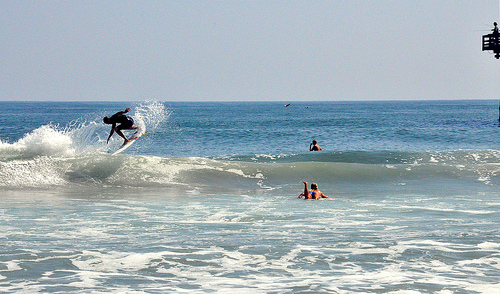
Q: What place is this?
A: It is an ocean.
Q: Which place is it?
A: It is an ocean.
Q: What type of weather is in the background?
A: It is clear.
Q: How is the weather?
A: It is clear.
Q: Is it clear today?
A: Yes, it is clear.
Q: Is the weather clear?
A: Yes, it is clear.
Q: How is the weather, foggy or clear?
A: It is clear.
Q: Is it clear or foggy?
A: It is clear.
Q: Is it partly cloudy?
A: No, it is clear.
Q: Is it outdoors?
A: Yes, it is outdoors.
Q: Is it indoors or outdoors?
A: It is outdoors.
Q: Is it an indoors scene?
A: No, it is outdoors.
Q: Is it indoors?
A: No, it is outdoors.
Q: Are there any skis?
A: No, there are no skis.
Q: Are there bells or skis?
A: No, there are no skis or bells.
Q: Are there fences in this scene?
A: No, there are no fences.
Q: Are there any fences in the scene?
A: No, there are no fences.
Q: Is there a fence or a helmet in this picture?
A: No, there are no fences or helmets.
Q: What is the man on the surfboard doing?
A: The man is surfing.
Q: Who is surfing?
A: The man is surfing.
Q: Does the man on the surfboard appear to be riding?
A: No, the man is surfing.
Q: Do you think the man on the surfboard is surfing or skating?
A: The man is surfing.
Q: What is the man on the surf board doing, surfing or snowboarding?
A: The man is surfing.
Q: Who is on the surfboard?
A: The man is on the surfboard.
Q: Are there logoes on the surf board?
A: No, there is a man on the surf board.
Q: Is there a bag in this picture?
A: No, there are no bags.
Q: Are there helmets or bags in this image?
A: No, there are no bags or helmets.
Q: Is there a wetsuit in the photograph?
A: Yes, there is a wetsuit.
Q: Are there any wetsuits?
A: Yes, there is a wetsuit.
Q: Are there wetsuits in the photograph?
A: Yes, there is a wetsuit.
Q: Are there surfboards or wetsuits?
A: Yes, there is a wetsuit.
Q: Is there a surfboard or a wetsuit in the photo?
A: Yes, there is a wetsuit.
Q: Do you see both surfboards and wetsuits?
A: Yes, there are both a wetsuit and a surfboard.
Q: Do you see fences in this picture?
A: No, there are no fences.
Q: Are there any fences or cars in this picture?
A: No, there are no fences or cars.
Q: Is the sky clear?
A: Yes, the sky is clear.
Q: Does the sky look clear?
A: Yes, the sky is clear.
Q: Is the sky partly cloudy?
A: No, the sky is clear.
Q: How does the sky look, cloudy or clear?
A: The sky is clear.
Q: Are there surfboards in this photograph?
A: Yes, there is a surfboard.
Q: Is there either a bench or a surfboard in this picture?
A: Yes, there is a surfboard.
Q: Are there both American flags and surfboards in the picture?
A: No, there is a surfboard but no American flags.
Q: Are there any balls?
A: No, there are no balls.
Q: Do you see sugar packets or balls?
A: No, there are no balls or sugar packets.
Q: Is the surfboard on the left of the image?
A: Yes, the surfboard is on the left of the image.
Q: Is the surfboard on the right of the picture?
A: No, the surfboard is on the left of the image.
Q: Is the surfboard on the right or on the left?
A: The surfboard is on the left of the image.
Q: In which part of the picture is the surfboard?
A: The surfboard is on the left of the image.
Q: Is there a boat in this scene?
A: No, there are no boats.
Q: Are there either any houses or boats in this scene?
A: No, there are no boats or houses.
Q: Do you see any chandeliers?
A: No, there are no chandeliers.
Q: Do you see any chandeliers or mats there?
A: No, there are no chandeliers or mats.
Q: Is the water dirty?
A: Yes, the water is dirty.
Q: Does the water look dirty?
A: Yes, the water is dirty.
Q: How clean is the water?
A: The water is dirty.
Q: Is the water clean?
A: No, the water is dirty.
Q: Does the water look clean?
A: No, the water is dirty.